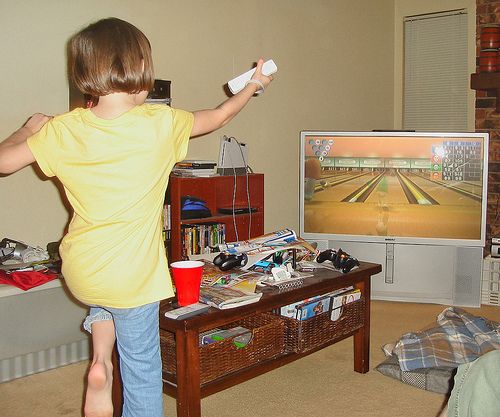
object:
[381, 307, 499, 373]
blanket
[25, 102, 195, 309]
shirt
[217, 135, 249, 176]
game system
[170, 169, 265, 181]
shelf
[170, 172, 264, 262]
bookshelf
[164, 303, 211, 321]
remote control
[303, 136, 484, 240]
game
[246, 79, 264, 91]
wristband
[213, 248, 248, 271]
remote control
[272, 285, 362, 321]
cases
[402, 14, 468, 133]
blinds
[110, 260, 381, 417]
coffee table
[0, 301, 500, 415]
carpet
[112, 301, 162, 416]
pant leg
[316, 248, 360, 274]
controller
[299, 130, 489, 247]
tv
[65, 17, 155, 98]
bob haircut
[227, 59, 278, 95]
control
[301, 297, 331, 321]
movies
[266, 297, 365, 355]
basket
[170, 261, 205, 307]
cup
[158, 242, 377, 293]
table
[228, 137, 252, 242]
cords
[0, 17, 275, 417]
child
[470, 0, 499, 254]
brick wall